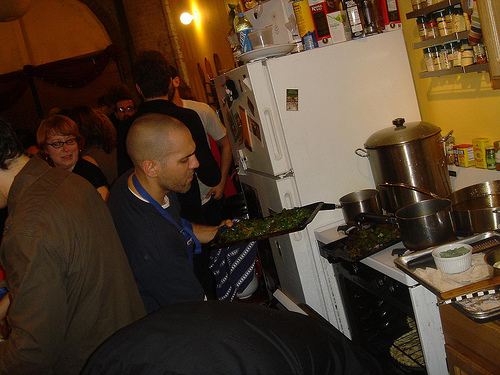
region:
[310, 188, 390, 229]
a metal pot on a stove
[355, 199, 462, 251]
a metal pot on a stove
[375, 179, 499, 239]
a large metal pot on a stove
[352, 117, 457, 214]
a large metal pot on a stove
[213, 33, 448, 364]
a white refridgerator in a kitchen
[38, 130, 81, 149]
a woman with glasses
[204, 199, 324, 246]
a man holding a metal tray with food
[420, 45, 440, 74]
a small bottle of seasoning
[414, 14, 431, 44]
a small bottle of seasoning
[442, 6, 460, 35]
a small bottle of seasoning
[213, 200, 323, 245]
Man holding a tray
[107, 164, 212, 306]
Man wearing a shirt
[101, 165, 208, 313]
Man is wearing a shirt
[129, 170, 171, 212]
Man wearing an undershirt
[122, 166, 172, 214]
Man is wearing an undershirt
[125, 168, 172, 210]
Man wearing a white undershirt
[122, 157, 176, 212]
Man is wearing a white undershirt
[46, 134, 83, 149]
Woman is wearing glasses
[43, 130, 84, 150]
Woman is wearing black glasses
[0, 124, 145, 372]
a person in a brown shirt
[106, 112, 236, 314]
a man in a navy blue sweat shirt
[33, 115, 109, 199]
a woman wearing a black shirt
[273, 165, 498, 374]
a white stove in the kitchen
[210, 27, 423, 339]
a white refrigerator freezer in kitchen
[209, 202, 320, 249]
a black cookie sheet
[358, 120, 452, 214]
a large silver pot on the stove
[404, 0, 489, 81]
a wooden spice rack on the wall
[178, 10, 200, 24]
a light fixture on the wall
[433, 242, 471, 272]
a white bowl on the counter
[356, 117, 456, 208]
a large pot on a stove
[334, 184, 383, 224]
a small pot on a stove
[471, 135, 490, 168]
a can of mustard on the back of a stove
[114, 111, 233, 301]
a man putting a tray into the oven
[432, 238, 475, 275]
a round white bowl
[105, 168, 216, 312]
a navy shirt on a man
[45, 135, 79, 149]
glasses on a woman's face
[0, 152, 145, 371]
a brown shirt on a man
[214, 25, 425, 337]
a white refrigerator next to a stove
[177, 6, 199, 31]
a light on a wall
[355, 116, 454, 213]
the tall metal pot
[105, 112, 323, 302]
the man with a pan in his hand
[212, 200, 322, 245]
the pan in the man's hand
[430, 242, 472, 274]
the small white ramekin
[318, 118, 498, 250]
the metal pots on the stove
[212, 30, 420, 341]
the refrigerator next to the stove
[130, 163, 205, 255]
the blue object around the man's neck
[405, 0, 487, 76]
the spice rack on the wall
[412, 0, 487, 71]
the spices on the rack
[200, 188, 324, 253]
a pan of food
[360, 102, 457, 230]
a large stove on the pot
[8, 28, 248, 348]
a group of people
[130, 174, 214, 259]
man wearing a blue lanyard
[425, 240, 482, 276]
ramekan on the counter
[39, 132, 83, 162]
a pair of glasses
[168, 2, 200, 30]
light on the wall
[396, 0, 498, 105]
spice rack on the wall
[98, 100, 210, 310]
the man is bald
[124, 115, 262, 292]
the man is holding a tray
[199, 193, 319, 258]
the tray has food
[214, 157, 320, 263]
the food is green